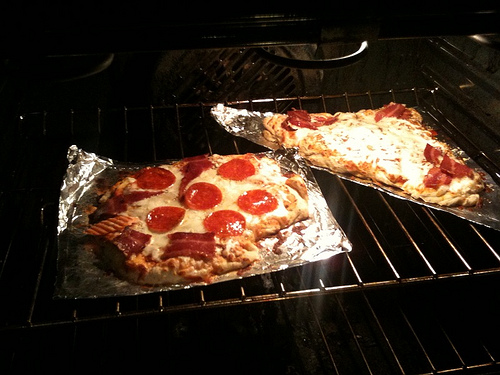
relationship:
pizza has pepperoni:
[56, 145, 315, 289] [133, 157, 278, 244]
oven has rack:
[0, 0, 500, 374] [1, 84, 500, 334]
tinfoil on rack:
[42, 93, 498, 305] [1, 84, 500, 334]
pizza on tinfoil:
[56, 145, 315, 289] [45, 144, 352, 301]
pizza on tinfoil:
[261, 97, 489, 211] [205, 97, 498, 235]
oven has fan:
[0, 0, 500, 374] [146, 35, 325, 144]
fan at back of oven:
[146, 35, 325, 144] [0, 0, 500, 374]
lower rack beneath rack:
[145, 120, 498, 374] [1, 84, 500, 334]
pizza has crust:
[56, 145, 315, 289] [86, 146, 312, 290]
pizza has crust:
[261, 97, 489, 211] [259, 96, 490, 212]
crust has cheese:
[86, 146, 312, 290] [115, 161, 289, 258]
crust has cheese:
[259, 96, 490, 212] [302, 115, 443, 185]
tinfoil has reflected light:
[45, 144, 352, 301] [59, 146, 352, 270]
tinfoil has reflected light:
[205, 97, 498, 235] [206, 97, 274, 138]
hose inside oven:
[49, 54, 117, 91] [0, 0, 500, 374]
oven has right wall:
[0, 0, 500, 374] [0, 55, 113, 373]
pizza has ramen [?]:
[261, 97, 489, 211] [319, 117, 432, 187]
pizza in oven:
[56, 145, 315, 289] [0, 0, 500, 374]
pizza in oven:
[261, 97, 489, 211] [0, 0, 500, 374]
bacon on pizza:
[95, 150, 218, 264] [56, 145, 315, 289]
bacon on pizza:
[279, 99, 483, 187] [261, 97, 489, 211]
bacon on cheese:
[95, 150, 218, 264] [115, 161, 289, 258]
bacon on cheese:
[279, 99, 483, 187] [302, 115, 443, 185]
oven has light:
[0, 0, 500, 374] [244, 33, 494, 91]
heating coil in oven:
[247, 40, 374, 75] [0, 0, 500, 374]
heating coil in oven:
[31, 53, 124, 91] [0, 0, 500, 374]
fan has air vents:
[146, 35, 325, 144] [177, 49, 294, 111]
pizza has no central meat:
[261, 97, 489, 211] [307, 124, 429, 186]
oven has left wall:
[0, 0, 500, 374] [415, 20, 499, 374]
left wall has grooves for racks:
[415, 20, 499, 374] [423, 35, 499, 179]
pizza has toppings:
[56, 145, 315, 289] [81, 153, 285, 262]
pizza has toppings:
[261, 97, 489, 211] [281, 99, 478, 188]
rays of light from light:
[272, 150, 369, 357] [244, 33, 372, 69]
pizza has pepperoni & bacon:
[56, 145, 315, 289] [73, 152, 275, 264]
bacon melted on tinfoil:
[159, 225, 218, 262] [45, 144, 352, 301]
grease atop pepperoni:
[155, 192, 270, 235] [133, 157, 278, 244]